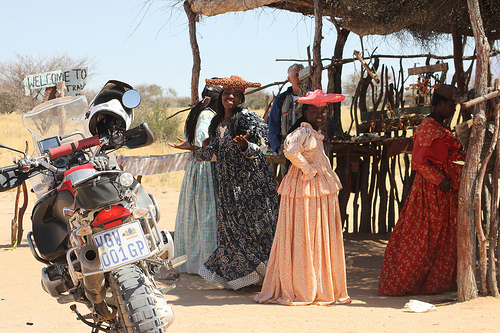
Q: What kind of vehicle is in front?
A: A motorcycle.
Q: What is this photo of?
A: Outside Event.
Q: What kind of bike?
A: A motorcycle.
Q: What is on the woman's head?
A: A hat.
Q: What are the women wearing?
A: Dresses.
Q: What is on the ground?
A: Sand.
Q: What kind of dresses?
A: Long dresses.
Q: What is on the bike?
A: Helmet.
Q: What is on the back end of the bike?
A: A license plate.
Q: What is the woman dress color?
A: Blue.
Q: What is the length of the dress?
A: Long.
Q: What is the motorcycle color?
A: Black.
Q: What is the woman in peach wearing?
A: A hat.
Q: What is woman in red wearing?
A: A dress.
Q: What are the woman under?
A: Long barks.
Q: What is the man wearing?
A: A shirt.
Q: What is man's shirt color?
A: Blue.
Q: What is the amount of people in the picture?
A: Five people.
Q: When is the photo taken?
A: Daytime.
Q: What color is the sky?
A: Blue.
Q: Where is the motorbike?
A: On the left.